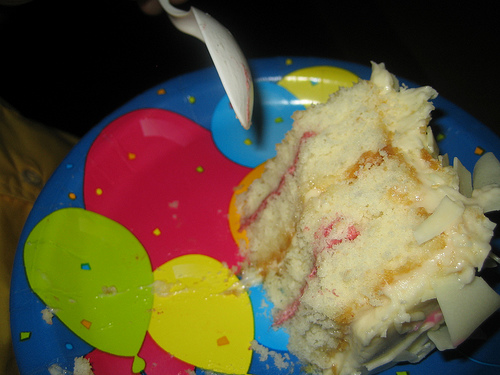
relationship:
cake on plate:
[238, 60, 497, 374] [9, 58, 500, 375]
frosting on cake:
[329, 59, 496, 374] [238, 60, 497, 374]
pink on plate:
[83, 107, 253, 375] [9, 58, 500, 375]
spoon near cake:
[158, 0, 255, 132] [238, 60, 497, 374]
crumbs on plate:
[41, 308, 297, 375] [9, 58, 500, 375]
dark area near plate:
[1, 1, 500, 141] [9, 58, 500, 375]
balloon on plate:
[85, 109, 255, 276] [9, 58, 500, 375]